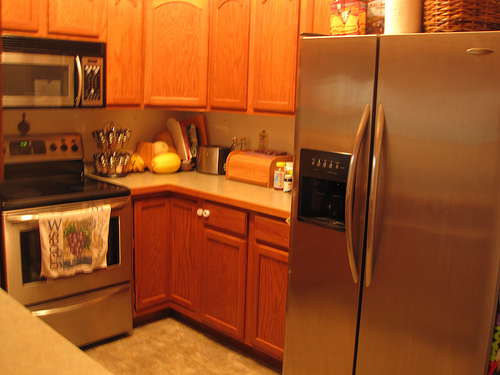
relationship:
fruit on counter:
[149, 155, 182, 174] [95, 164, 293, 211]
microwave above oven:
[0, 43, 107, 110] [0, 134, 128, 350]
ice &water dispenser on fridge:
[298, 144, 353, 230] [279, 31, 497, 374]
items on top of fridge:
[328, 1, 499, 36] [279, 31, 497, 374]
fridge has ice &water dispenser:
[279, 31, 497, 374] [298, 144, 353, 230]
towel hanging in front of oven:
[40, 203, 112, 279] [0, 134, 128, 350]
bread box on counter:
[224, 151, 288, 186] [95, 164, 293, 211]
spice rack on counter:
[93, 120, 133, 180] [95, 164, 293, 211]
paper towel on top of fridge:
[383, 1, 424, 35] [279, 31, 497, 374]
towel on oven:
[40, 203, 112, 279] [0, 134, 128, 350]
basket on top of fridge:
[421, 0, 499, 32] [279, 31, 497, 374]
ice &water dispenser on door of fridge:
[298, 144, 353, 230] [279, 31, 497, 374]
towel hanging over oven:
[40, 203, 112, 279] [0, 134, 128, 350]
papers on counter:
[167, 117, 208, 160] [95, 164, 293, 211]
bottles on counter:
[273, 162, 293, 191] [95, 164, 293, 211]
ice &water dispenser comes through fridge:
[298, 144, 353, 230] [279, 31, 497, 374]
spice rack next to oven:
[93, 120, 133, 180] [0, 134, 128, 350]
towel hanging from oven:
[40, 203, 112, 279] [5, 196, 132, 307]